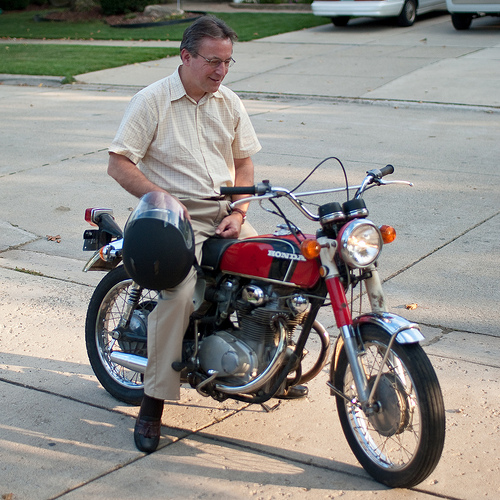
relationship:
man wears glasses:
[113, 15, 274, 410] [177, 34, 241, 72]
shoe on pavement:
[112, 388, 170, 458] [3, 95, 489, 498]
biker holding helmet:
[113, 15, 274, 410] [83, 166, 208, 308]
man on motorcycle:
[113, 15, 274, 410] [82, 163, 442, 475]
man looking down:
[113, 15, 274, 410] [72, 160, 377, 320]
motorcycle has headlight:
[82, 163, 442, 475] [301, 208, 417, 285]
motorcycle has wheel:
[82, 163, 442, 475] [286, 300, 473, 497]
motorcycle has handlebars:
[82, 163, 442, 475] [201, 165, 398, 205]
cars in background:
[269, 5, 499, 35] [8, 1, 490, 87]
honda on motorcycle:
[253, 236, 316, 266] [82, 163, 442, 475]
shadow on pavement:
[12, 352, 467, 496] [3, 95, 489, 498]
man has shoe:
[113, 15, 274, 410] [112, 388, 170, 458]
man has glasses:
[113, 15, 274, 410] [177, 34, 241, 72]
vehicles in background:
[317, 8, 499, 44] [8, 1, 490, 87]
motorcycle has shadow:
[82, 163, 442, 475] [12, 352, 467, 496]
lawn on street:
[10, 0, 310, 104] [4, 50, 496, 251]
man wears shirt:
[113, 15, 274, 410] [83, 43, 265, 225]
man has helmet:
[113, 15, 274, 410] [83, 166, 208, 308]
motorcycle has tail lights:
[82, 163, 442, 475] [76, 182, 116, 264]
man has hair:
[113, 15, 274, 410] [169, 7, 237, 66]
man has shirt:
[113, 15, 274, 410] [83, 43, 265, 225]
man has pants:
[113, 15, 274, 410] [133, 174, 262, 409]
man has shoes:
[113, 15, 274, 410] [109, 369, 185, 464]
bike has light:
[82, 163, 442, 475] [328, 211, 387, 277]